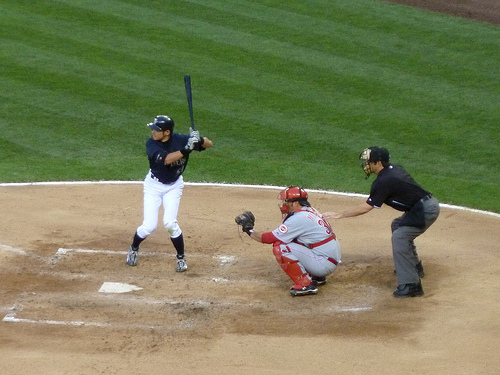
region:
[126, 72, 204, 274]
baeball batter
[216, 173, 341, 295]
baseball catcher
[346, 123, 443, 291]
baseball umpire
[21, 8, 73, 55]
short dark and light green grass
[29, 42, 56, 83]
short dark and light green grass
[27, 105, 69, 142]
short dark and light green grass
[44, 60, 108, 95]
short dark and light green grass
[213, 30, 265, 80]
short dark and light green grass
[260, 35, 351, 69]
short dark and light green grass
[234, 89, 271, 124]
short dark and light green grass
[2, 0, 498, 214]
green grass on the baseball field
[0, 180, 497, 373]
dirt on the baseball field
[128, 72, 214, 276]
baseball player batting a baseball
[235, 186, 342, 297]
baseball catcher wearing red and grey uniform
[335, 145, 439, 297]
baseball umpire wearing a black shirt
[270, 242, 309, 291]
baseball catcher's wearing red shin guards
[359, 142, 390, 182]
umpire's black hat and protective face mask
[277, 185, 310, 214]
baseball catcher's red protective helmet and mask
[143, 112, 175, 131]
baseball batter's black protective helmet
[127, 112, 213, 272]
baseball player wearing a black and white uniform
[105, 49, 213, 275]
The batter is readying to hit the ball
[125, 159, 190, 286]
his uniform pants are white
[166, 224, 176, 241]
he has dirt on the knee of his pants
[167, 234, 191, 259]
his socks are blue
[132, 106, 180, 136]
he is wearing a batters helmet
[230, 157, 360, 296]
the catcher is squating behind the batter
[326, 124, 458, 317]
the umpire is standing behind the catcher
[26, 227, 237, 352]
the batter is standing in the batters box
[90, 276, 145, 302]
this triangle represents home plate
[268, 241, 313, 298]
the catchers safety gear is red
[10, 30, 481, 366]
The people are on a baseball field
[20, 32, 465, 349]
The people are playing a baseball game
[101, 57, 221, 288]
A man is trying to hit a baseball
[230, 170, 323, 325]
A man is trying to catch a baseball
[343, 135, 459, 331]
The man is a baseball umpire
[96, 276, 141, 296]
Home plate on a baseball field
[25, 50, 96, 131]
The grass on a baseball field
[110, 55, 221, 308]
The man is wearing a helmet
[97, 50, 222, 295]
The man is holding a baseball bat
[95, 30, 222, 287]
The man is wearing white pants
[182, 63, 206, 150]
the bat is black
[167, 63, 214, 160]
the bat is black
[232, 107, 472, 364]
an umpire behind the catcher